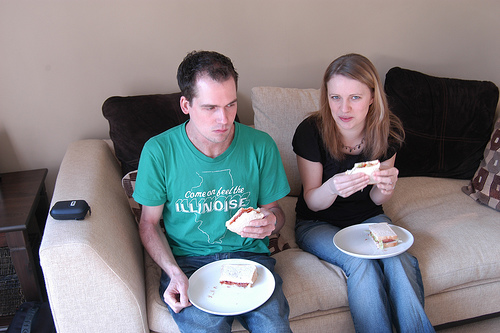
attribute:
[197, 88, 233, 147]
man — angry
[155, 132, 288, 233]
green shirt — green 